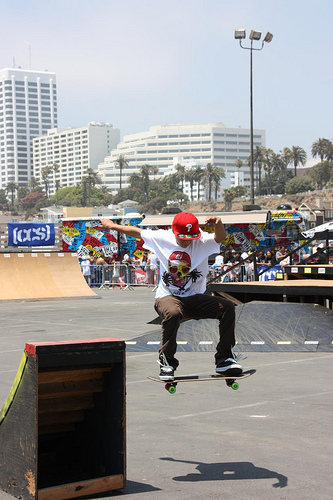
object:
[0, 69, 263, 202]
building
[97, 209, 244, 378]
man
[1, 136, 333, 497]
park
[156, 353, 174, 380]
shoe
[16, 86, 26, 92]
window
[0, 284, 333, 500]
court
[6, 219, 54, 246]
sign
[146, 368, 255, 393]
board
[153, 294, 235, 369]
trouser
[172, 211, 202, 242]
cap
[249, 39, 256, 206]
light pole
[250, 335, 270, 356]
white dash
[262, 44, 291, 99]
ground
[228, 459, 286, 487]
shadow part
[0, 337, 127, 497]
ramp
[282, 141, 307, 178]
tree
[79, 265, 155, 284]
fence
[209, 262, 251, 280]
fence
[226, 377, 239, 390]
wheel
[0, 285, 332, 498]
surface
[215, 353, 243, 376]
shoe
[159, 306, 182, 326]
knee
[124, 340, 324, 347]
white dash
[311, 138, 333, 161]
trees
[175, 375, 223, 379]
board part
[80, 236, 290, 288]
spectators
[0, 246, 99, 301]
ramp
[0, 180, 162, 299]
distance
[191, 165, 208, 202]
palm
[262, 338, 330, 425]
part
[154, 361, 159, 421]
part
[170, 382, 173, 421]
part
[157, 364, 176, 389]
part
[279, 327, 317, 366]
part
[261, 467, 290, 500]
part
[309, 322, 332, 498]
edge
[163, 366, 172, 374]
tip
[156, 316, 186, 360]
part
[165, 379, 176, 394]
wheel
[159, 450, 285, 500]
shadow